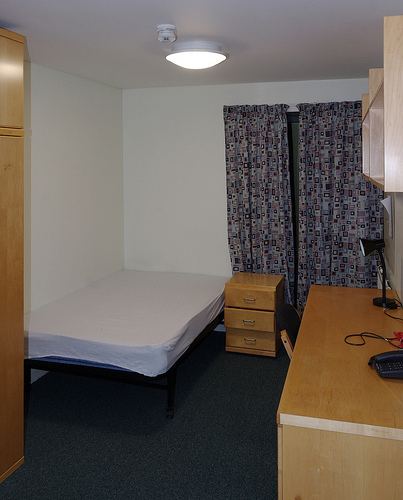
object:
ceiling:
[297, 57, 345, 85]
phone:
[366, 348, 390, 375]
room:
[4, 65, 390, 470]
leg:
[155, 372, 180, 422]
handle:
[241, 297, 256, 302]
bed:
[33, 271, 244, 415]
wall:
[25, 58, 131, 322]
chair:
[270, 303, 302, 361]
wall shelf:
[354, 12, 399, 196]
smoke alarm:
[154, 17, 175, 41]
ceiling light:
[159, 45, 232, 75]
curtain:
[220, 99, 366, 315]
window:
[226, 109, 369, 306]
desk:
[276, 279, 402, 497]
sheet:
[28, 258, 228, 372]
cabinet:
[222, 275, 282, 357]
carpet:
[237, 469, 277, 497]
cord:
[343, 319, 384, 347]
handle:
[235, 314, 259, 327]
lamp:
[357, 237, 398, 310]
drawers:
[222, 304, 277, 331]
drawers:
[223, 280, 277, 312]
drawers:
[215, 325, 283, 357]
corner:
[95, 71, 150, 130]